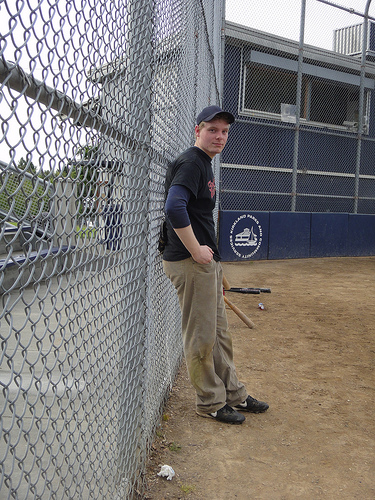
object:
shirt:
[157, 144, 220, 264]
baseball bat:
[218, 294, 256, 329]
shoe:
[195, 405, 246, 426]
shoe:
[225, 392, 270, 413]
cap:
[194, 103, 236, 126]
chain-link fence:
[0, 1, 227, 500]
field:
[129, 255, 374, 497]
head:
[194, 104, 231, 154]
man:
[156, 103, 273, 424]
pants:
[162, 258, 249, 416]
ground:
[130, 256, 375, 498]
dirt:
[138, 255, 374, 497]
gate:
[0, 0, 225, 498]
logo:
[228, 211, 265, 261]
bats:
[223, 287, 261, 294]